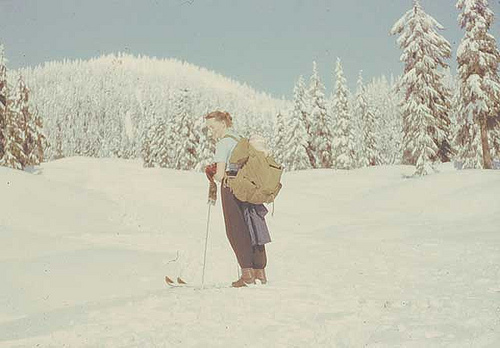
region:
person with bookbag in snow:
[193, 96, 275, 297]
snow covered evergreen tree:
[385, 7, 450, 179]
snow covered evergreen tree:
[453, 1, 499, 165]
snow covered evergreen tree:
[351, 82, 374, 167]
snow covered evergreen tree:
[330, 57, 350, 172]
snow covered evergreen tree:
[307, 66, 324, 171]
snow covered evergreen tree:
[3, 75, 45, 165]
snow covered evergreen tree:
[138, 122, 168, 164]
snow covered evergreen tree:
[164, 70, 197, 160]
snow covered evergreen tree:
[358, 90, 382, 159]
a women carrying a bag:
[231, 138, 283, 198]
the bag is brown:
[238, 163, 285, 205]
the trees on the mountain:
[95, 80, 187, 140]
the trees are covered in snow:
[65, 85, 165, 137]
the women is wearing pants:
[218, 205, 251, 236]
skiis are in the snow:
[157, 270, 202, 295]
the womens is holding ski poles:
[201, 210, 217, 236]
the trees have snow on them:
[405, 90, 445, 161]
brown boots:
[231, 270, 256, 283]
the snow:
[31, 171, 134, 243]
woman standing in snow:
[194, 104, 294, 298]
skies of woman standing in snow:
[160, 269, 275, 294]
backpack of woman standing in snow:
[222, 132, 285, 214]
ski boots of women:
[222, 261, 274, 289]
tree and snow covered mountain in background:
[43, 53, 278, 164]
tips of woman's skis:
[160, 271, 192, 295]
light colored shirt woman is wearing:
[210, 141, 253, 164]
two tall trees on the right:
[398, 3, 498, 168]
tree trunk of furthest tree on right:
[473, 120, 497, 160]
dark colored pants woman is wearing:
[220, 175, 272, 271]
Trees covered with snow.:
[13, 11, 487, 166]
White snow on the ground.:
[303, 190, 473, 322]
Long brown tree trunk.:
[476, 109, 494, 169]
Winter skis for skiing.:
[156, 272, 275, 292]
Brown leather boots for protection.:
[232, 265, 274, 290]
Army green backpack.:
[227, 138, 288, 206]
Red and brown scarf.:
[203, 163, 220, 208]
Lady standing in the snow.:
[169, 102, 286, 297]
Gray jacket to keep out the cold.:
[238, 198, 279, 249]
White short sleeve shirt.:
[214, 132, 241, 174]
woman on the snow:
[179, 92, 322, 309]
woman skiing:
[139, 89, 329, 305]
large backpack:
[218, 133, 294, 213]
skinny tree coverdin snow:
[389, 5, 464, 165]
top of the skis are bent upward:
[159, 266, 189, 293]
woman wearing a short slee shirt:
[200, 105, 251, 186]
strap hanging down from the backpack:
[266, 190, 282, 221]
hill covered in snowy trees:
[12, 32, 294, 151]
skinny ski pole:
[197, 192, 217, 295]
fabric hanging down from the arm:
[200, 153, 232, 203]